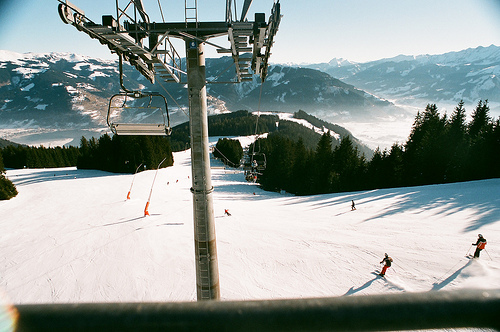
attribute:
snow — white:
[37, 268, 197, 280]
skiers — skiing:
[368, 246, 498, 280]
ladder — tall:
[169, 9, 237, 289]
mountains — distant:
[303, 36, 495, 163]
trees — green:
[393, 70, 469, 160]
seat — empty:
[107, 88, 185, 180]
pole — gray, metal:
[33, 300, 485, 324]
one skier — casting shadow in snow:
[376, 250, 391, 280]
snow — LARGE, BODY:
[242, 235, 283, 283]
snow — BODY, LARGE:
[271, 235, 328, 283]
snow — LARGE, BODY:
[265, 235, 311, 291]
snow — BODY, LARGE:
[263, 239, 325, 277]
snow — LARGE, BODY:
[322, 225, 379, 254]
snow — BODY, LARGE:
[246, 219, 325, 297]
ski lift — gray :
[55, 0, 285, 313]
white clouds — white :
[322, 11, 362, 43]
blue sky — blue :
[315, 6, 419, 41]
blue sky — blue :
[335, 5, 434, 41]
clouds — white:
[314, 27, 372, 69]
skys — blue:
[342, 41, 389, 44]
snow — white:
[247, 218, 309, 248]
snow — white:
[53, 248, 133, 296]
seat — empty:
[87, 69, 177, 124]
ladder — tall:
[179, 203, 227, 311]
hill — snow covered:
[17, 198, 360, 288]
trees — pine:
[244, 96, 474, 187]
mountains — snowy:
[11, 40, 437, 120]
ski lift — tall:
[97, 79, 260, 219]